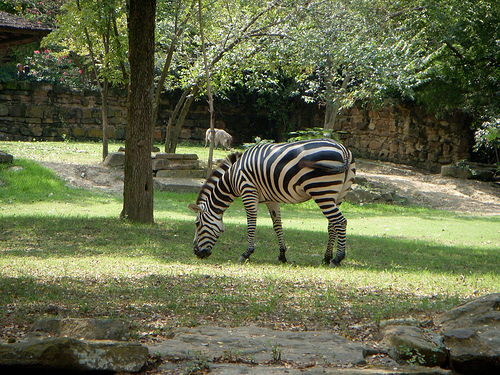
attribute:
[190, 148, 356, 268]
zebra — eating, small, grazing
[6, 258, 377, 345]
grass — faded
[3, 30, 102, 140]
stone wall — black, brown, aging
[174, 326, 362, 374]
rocks — grey, dirty